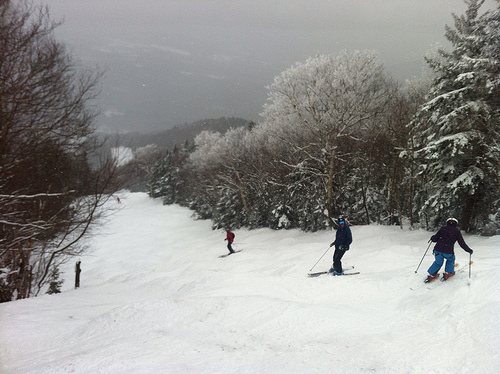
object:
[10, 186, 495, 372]
slope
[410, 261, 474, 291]
skis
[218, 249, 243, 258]
skis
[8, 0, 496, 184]
mountains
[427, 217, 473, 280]
people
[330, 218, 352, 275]
people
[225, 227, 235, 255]
people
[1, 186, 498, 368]
snow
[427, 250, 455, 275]
ski pants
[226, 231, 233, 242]
coat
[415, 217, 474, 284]
ski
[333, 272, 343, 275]
feet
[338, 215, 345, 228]
blue hat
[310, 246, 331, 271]
poles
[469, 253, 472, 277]
pole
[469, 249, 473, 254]
hand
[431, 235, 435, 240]
hand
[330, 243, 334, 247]
hand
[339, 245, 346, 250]
hand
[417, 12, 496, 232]
tree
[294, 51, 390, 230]
tree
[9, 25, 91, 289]
tree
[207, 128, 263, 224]
tree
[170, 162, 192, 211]
tree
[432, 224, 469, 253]
jacket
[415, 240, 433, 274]
pole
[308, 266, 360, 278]
skis